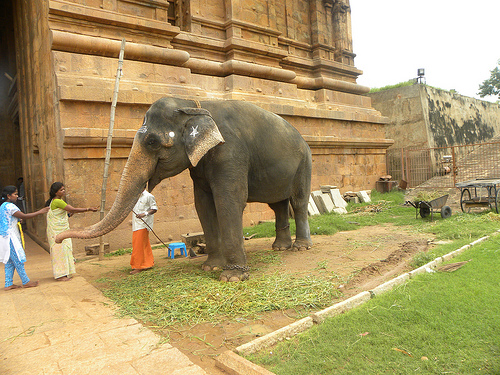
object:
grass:
[265, 249, 495, 368]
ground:
[199, 246, 496, 357]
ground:
[369, 229, 399, 274]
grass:
[430, 344, 500, 375]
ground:
[83, 299, 169, 364]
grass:
[139, 292, 197, 321]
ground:
[94, 357, 186, 375]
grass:
[138, 272, 189, 313]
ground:
[147, 306, 428, 358]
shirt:
[51, 199, 68, 211]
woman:
[45, 182, 98, 281]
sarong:
[46, 198, 76, 279]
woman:
[0, 185, 50, 291]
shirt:
[0, 202, 27, 265]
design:
[0, 185, 50, 290]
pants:
[4, 238, 30, 288]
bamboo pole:
[99, 38, 126, 261]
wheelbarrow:
[404, 194, 452, 222]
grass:
[453, 239, 472, 303]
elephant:
[54, 96, 312, 282]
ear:
[173, 108, 225, 167]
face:
[138, 96, 180, 193]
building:
[0, 0, 395, 256]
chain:
[223, 264, 249, 272]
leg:
[208, 169, 248, 260]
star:
[190, 125, 200, 137]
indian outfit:
[0, 201, 30, 287]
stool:
[168, 242, 187, 259]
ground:
[23, 323, 58, 375]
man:
[130, 183, 158, 274]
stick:
[132, 210, 172, 251]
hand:
[136, 213, 145, 219]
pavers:
[306, 183, 410, 256]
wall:
[229, 0, 264, 23]